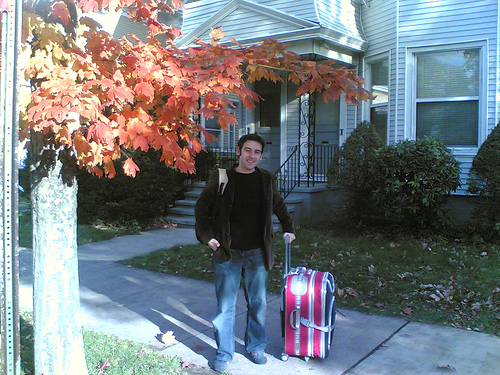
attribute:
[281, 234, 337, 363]
suitcase — gray, black, pink, blue, red, white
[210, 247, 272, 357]
jeans — medium wash, blue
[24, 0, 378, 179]
leaves — orange, red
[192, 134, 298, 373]
man — smiling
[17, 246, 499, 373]
sidewalk — cement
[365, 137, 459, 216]
bush — green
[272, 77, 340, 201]
railing — iron, black, metal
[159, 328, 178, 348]
leaf — brown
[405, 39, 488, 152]
window — glass, closed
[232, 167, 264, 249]
shirt — black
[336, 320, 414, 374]
line — dark